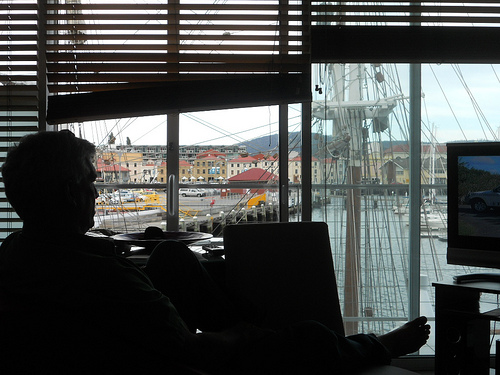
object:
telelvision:
[442, 138, 497, 268]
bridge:
[176, 200, 283, 234]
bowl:
[111, 225, 213, 249]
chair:
[216, 215, 357, 339]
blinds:
[0, 0, 499, 245]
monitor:
[440, 140, 498, 270]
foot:
[369, 314, 431, 358]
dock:
[96, 179, 336, 231]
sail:
[297, 55, 451, 350]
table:
[122, 233, 227, 267]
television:
[444, 140, 498, 273]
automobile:
[468, 186, 498, 217]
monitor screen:
[458, 154, 499, 234]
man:
[0, 127, 432, 374]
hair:
[2, 149, 73, 222]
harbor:
[79, 163, 328, 235]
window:
[1, 1, 39, 250]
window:
[54, 1, 309, 236]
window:
[310, 2, 498, 355]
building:
[92, 143, 451, 228]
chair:
[10, 263, 190, 374]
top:
[229, 166, 280, 182]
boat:
[296, 61, 499, 357]